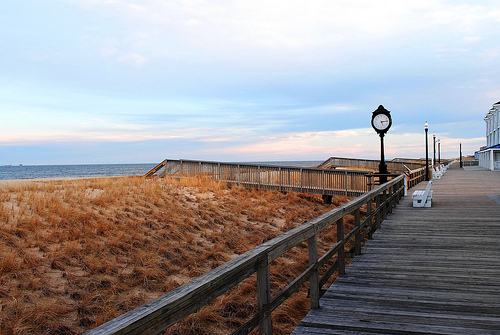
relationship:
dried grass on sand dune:
[90, 200, 190, 271] [3, 173, 375, 333]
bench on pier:
[430, 168, 448, 178] [278, 126, 489, 246]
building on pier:
[460, 100, 497, 183] [396, 122, 478, 197]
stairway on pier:
[136, 162, 268, 177] [278, 124, 498, 331]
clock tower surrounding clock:
[371, 104, 393, 185] [372, 112, 389, 131]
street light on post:
[411, 114, 431, 137] [420, 110, 440, 182]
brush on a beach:
[40, 203, 289, 260] [6, 156, 278, 268]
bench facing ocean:
[410, 175, 436, 210] [20, 160, 122, 172]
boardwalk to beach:
[145, 157, 394, 194] [16, 176, 307, 181]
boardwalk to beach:
[311, 157, 424, 174] [16, 176, 307, 181]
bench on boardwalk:
[411, 178, 438, 209] [293, 162, 494, 331]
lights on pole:
[419, 115, 445, 191] [422, 129, 432, 186]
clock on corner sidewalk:
[372, 113, 389, 130] [290, 168, 499, 330]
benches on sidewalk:
[406, 157, 471, 212] [84, 140, 499, 332]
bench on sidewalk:
[410, 178, 433, 207] [290, 168, 499, 330]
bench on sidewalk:
[431, 167, 440, 177] [290, 168, 499, 330]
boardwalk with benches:
[287, 162, 499, 335] [410, 156, 466, 219]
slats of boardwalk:
[392, 226, 469, 313] [265, 164, 498, 333]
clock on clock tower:
[374, 113, 387, 132] [135, 2, 330, 132]